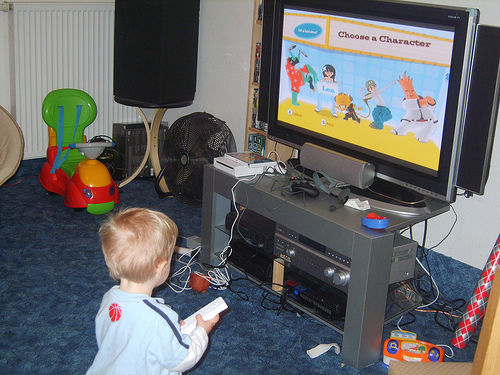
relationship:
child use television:
[71, 207, 221, 373] [247, 7, 459, 182]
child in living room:
[71, 207, 221, 373] [4, 0, 482, 374]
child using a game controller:
[71, 207, 221, 373] [181, 282, 233, 339]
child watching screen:
[71, 197, 231, 373] [274, 10, 481, 200]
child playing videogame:
[71, 207, 221, 373] [386, 292, 483, 363]